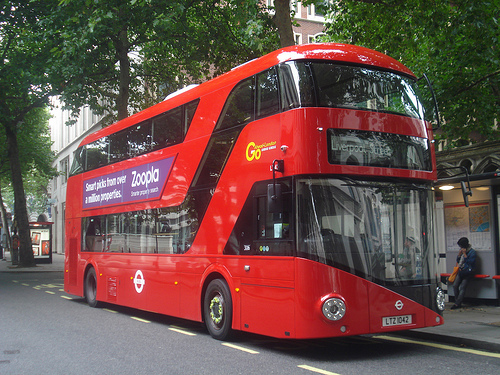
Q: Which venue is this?
A: This is a street.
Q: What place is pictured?
A: It is a street.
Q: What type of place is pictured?
A: It is a street.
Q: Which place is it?
A: It is a street.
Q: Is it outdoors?
A: Yes, it is outdoors.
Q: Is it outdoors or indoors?
A: It is outdoors.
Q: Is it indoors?
A: No, it is outdoors.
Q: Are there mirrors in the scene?
A: Yes, there is a mirror.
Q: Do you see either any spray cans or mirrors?
A: Yes, there is a mirror.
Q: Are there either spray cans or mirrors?
A: Yes, there is a mirror.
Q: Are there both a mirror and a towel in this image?
A: No, there is a mirror but no towels.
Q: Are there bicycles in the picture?
A: No, there are no bicycles.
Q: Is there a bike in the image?
A: No, there are no bikes.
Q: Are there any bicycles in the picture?
A: No, there are no bicycles.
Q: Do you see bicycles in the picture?
A: No, there are no bicycles.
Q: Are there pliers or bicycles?
A: No, there are no bicycles or pliers.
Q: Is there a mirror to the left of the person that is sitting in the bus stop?
A: Yes, there is a mirror to the left of the person.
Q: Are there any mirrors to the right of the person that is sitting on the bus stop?
A: No, the mirror is to the left of the person.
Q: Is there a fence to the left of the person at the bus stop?
A: No, there is a mirror to the left of the person.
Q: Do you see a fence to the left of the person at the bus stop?
A: No, there is a mirror to the left of the person.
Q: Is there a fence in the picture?
A: No, there are no fences.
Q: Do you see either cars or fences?
A: No, there are no fences or cars.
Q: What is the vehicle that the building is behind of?
A: The vehicle is a bus.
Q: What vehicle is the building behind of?
A: The building is behind the bus.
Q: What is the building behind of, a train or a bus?
A: The building is behind a bus.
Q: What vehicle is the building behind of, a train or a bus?
A: The building is behind a bus.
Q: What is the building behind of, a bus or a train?
A: The building is behind a bus.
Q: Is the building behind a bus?
A: Yes, the building is behind a bus.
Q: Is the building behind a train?
A: No, the building is behind a bus.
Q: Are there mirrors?
A: Yes, there is a mirror.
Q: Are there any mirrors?
A: Yes, there is a mirror.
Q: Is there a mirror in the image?
A: Yes, there is a mirror.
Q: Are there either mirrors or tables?
A: Yes, there is a mirror.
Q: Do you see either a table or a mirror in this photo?
A: Yes, there is a mirror.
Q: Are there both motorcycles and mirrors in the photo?
A: No, there is a mirror but no motorcycles.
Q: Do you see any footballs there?
A: No, there are no footballs.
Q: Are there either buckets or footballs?
A: No, there are no footballs or buckets.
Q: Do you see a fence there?
A: No, there are no fences.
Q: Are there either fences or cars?
A: No, there are no fences or cars.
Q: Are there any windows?
A: Yes, there is a window.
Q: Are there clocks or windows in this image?
A: Yes, there is a window.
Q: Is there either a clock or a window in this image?
A: Yes, there is a window.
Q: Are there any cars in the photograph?
A: No, there are no cars.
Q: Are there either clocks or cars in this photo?
A: No, there are no cars or clocks.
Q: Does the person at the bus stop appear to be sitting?
A: Yes, the person is sitting.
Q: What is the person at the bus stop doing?
A: The person is sitting.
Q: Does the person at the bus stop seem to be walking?
A: No, the person is sitting.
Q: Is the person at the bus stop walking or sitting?
A: The person is sitting.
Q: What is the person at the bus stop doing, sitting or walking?
A: The person is sitting.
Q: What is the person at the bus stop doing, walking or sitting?
A: The person is sitting.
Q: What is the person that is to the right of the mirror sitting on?
A: The person is sitting on the bus stop.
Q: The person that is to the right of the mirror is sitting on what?
A: The person is sitting on the bus stop.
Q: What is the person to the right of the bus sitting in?
A: The person is sitting in the bus stop.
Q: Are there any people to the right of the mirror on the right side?
A: Yes, there is a person to the right of the mirror.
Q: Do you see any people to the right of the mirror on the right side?
A: Yes, there is a person to the right of the mirror.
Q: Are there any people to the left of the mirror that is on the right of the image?
A: No, the person is to the right of the mirror.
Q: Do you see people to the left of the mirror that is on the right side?
A: No, the person is to the right of the mirror.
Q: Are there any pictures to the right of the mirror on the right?
A: No, there is a person to the right of the mirror.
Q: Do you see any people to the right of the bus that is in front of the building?
A: Yes, there is a person to the right of the bus.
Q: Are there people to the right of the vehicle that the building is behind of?
A: Yes, there is a person to the right of the bus.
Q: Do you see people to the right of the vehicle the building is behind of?
A: Yes, there is a person to the right of the bus.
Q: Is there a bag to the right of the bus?
A: No, there is a person to the right of the bus.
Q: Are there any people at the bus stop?
A: Yes, there is a person at the bus stop.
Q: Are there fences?
A: No, there are no fences.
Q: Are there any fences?
A: No, there are no fences.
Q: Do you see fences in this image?
A: No, there are no fences.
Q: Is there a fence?
A: No, there are no fences.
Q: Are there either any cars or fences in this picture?
A: No, there are no fences or cars.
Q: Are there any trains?
A: No, there are no trains.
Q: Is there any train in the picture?
A: No, there are no trains.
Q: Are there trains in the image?
A: No, there are no trains.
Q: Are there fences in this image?
A: No, there are no fences.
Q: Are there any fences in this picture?
A: No, there are no fences.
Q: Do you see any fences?
A: No, there are no fences.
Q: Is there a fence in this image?
A: No, there are no fences.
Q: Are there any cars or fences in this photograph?
A: No, there are no fences or cars.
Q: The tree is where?
A: The tree is on the walkway.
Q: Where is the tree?
A: The tree is on the walkway.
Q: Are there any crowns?
A: No, there are no crowns.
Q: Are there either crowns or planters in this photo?
A: No, there are no crowns or planters.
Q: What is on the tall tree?
A: The leaves are on the tree.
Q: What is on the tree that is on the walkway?
A: The leaves are on the tree.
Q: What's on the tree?
A: The leaves are on the tree.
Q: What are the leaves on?
A: The leaves are on the tree.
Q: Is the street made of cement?
A: Yes, the street is made of cement.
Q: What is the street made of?
A: The street is made of concrete.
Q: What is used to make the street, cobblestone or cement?
A: The street is made of cement.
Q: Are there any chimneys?
A: No, there are no chimneys.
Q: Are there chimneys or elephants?
A: No, there are no chimneys or elephants.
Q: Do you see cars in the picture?
A: No, there are no cars.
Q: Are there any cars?
A: No, there are no cars.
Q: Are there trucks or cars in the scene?
A: No, there are no cars or trucks.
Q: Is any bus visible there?
A: Yes, there is a bus.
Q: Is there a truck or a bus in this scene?
A: Yes, there is a bus.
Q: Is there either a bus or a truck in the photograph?
A: Yes, there is a bus.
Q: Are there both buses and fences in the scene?
A: No, there is a bus but no fences.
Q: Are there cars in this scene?
A: No, there are no cars.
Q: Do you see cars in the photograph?
A: No, there are no cars.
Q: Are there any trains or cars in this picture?
A: No, there are no cars or trains.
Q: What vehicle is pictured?
A: The vehicle is a bus.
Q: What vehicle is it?
A: The vehicle is a bus.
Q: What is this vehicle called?
A: This is a bus.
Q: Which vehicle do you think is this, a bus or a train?
A: This is a bus.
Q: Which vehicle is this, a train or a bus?
A: This is a bus.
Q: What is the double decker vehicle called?
A: The vehicle is a bus.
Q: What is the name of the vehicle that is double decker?
A: The vehicle is a bus.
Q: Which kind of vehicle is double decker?
A: The vehicle is a bus.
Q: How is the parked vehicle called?
A: The vehicle is a bus.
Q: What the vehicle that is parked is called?
A: The vehicle is a bus.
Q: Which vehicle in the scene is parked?
A: The vehicle is a bus.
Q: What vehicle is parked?
A: The vehicle is a bus.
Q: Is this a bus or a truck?
A: This is a bus.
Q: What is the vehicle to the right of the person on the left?
A: The vehicle is a bus.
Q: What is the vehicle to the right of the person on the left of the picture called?
A: The vehicle is a bus.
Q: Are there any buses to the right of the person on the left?
A: Yes, there is a bus to the right of the person.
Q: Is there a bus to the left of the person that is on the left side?
A: No, the bus is to the right of the person.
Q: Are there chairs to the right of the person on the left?
A: No, there is a bus to the right of the person.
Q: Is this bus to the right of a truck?
A: No, the bus is to the right of a person.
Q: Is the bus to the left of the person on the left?
A: No, the bus is to the right of the person.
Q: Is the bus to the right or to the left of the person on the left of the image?
A: The bus is to the right of the person.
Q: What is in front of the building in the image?
A: The bus is in front of the building.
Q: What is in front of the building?
A: The bus is in front of the building.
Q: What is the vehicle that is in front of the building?
A: The vehicle is a bus.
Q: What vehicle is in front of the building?
A: The vehicle is a bus.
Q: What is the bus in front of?
A: The bus is in front of the building.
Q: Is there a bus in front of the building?
A: Yes, there is a bus in front of the building.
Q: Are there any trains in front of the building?
A: No, there is a bus in front of the building.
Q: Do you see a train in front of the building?
A: No, there is a bus in front of the building.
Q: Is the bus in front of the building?
A: Yes, the bus is in front of the building.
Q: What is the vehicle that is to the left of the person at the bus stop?
A: The vehicle is a bus.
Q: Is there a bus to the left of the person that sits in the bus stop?
A: Yes, there is a bus to the left of the person.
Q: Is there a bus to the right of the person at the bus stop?
A: No, the bus is to the left of the person.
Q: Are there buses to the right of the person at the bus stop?
A: No, the bus is to the left of the person.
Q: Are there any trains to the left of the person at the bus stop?
A: No, there is a bus to the left of the person.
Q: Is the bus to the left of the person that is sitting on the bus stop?
A: Yes, the bus is to the left of the person.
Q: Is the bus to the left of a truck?
A: No, the bus is to the left of the person.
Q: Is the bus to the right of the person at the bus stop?
A: No, the bus is to the left of the person.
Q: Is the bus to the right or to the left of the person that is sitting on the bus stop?
A: The bus is to the left of the person.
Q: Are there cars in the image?
A: No, there are no cars.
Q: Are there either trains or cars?
A: No, there are no cars or trains.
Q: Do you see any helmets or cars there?
A: No, there are no cars or helmets.